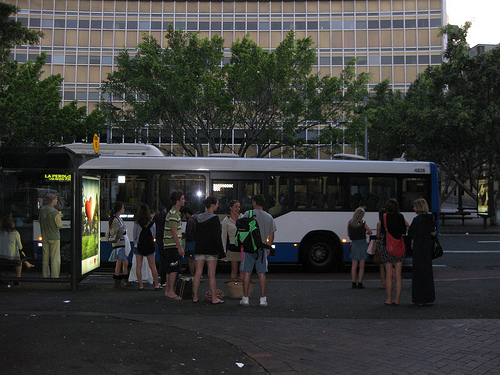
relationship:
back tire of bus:
[301, 236, 339, 273] [35, 126, 435, 256]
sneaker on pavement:
[257, 297, 270, 310] [32, 305, 498, 370]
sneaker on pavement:
[242, 296, 254, 306] [32, 305, 498, 370]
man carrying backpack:
[231, 204, 291, 314] [229, 221, 266, 251]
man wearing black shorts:
[157, 188, 192, 303] [158, 245, 182, 272]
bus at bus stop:
[80, 154, 438, 274] [31, 168, 120, 282]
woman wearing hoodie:
[190, 189, 230, 307] [180, 195, 232, 261]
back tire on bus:
[299, 233, 336, 268] [80, 154, 438, 274]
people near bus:
[136, 195, 253, 270] [91, 147, 417, 227]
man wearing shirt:
[163, 191, 186, 300] [163, 209, 180, 245]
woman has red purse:
[379, 195, 408, 307] [381, 213, 407, 256]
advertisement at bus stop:
[45, 135, 137, 305] [9, 136, 462, 299]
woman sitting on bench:
[2, 215, 36, 288] [4, 259, 26, 287]